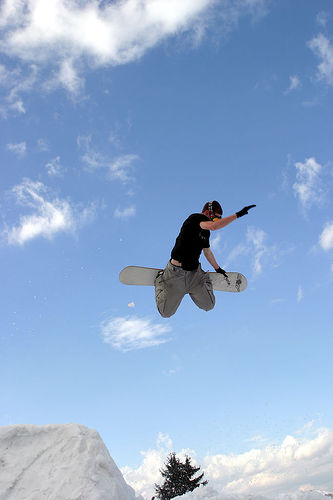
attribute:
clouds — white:
[26, 3, 151, 51]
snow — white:
[8, 429, 94, 494]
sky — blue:
[54, 365, 305, 416]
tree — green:
[151, 449, 204, 496]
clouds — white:
[235, 448, 330, 483]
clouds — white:
[8, 3, 189, 42]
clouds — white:
[9, 62, 128, 241]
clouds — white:
[94, 315, 164, 350]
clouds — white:
[264, 21, 331, 282]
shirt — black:
[174, 216, 210, 268]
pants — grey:
[152, 264, 215, 316]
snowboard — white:
[120, 265, 250, 294]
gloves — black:
[234, 201, 256, 217]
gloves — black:
[211, 266, 229, 279]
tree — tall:
[154, 451, 204, 498]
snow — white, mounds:
[3, 425, 124, 498]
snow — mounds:
[2, 428, 139, 497]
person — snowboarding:
[159, 201, 254, 315]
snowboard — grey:
[117, 257, 255, 298]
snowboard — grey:
[112, 263, 256, 291]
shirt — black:
[168, 213, 211, 265]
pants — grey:
[157, 264, 215, 323]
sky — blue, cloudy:
[3, 7, 328, 191]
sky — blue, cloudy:
[7, 316, 331, 423]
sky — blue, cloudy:
[168, 329, 332, 460]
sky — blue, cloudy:
[211, 409, 329, 494]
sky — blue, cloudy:
[168, 18, 329, 196]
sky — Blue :
[21, 65, 303, 436]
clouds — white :
[57, 261, 181, 367]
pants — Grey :
[137, 273, 246, 352]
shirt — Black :
[168, 223, 193, 257]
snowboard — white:
[109, 243, 260, 301]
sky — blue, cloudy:
[17, 50, 317, 302]